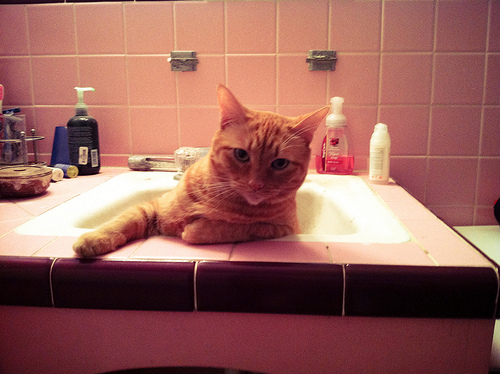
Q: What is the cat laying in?
A: A sink.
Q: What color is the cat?
A: Orange.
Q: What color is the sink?
A: White.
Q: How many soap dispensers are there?
A: Two.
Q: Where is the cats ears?
A: On its head.